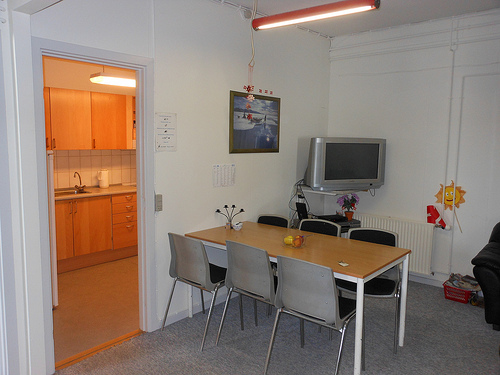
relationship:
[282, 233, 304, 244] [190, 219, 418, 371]
produce resting on table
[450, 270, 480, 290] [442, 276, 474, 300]
objects inside baskets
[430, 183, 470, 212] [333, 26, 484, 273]
sun on wall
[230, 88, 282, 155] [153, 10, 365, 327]
painting hanging on wall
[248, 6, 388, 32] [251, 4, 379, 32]
light fixture with light fixture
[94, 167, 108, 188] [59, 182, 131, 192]
pitcher on counter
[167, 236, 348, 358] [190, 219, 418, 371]
chairs around table